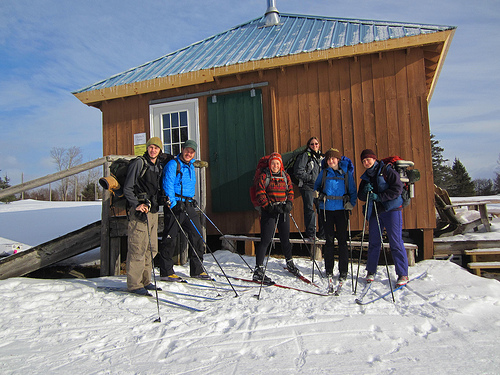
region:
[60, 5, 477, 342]
six people ready to ski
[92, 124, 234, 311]
two men with skis and backpacks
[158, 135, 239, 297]
a skier with a blue jacket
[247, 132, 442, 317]
four women with skis and backpacks on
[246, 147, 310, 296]
woman skier with a red backpack and hat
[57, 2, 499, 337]
skiers in front of a hut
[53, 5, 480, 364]
skiers ready to start their day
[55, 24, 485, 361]
five people with skis and one without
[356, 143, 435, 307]
woman dressed in blue with a red backpack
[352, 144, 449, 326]
a skier dressed in blue with a red backpack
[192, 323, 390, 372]
snow covering the ground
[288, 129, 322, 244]
person standing on a bench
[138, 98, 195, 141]
white door on the building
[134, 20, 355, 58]
tin roof on the building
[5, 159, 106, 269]
ramp up to the building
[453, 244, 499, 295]
steps to the building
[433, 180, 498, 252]
wooden chair on the deck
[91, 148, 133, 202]
back pack on the guy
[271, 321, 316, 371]
floor is white in color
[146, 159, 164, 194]
jacket is black in color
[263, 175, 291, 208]
jacket is red in color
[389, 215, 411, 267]
pants are purple in color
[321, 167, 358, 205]
jacket is blue in color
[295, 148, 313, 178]
jacket is grey in color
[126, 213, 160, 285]
pants are grey in color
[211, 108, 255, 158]
door is green in color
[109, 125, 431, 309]
a group of people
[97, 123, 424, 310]
people standing on the snow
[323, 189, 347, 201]
gray strap around the waist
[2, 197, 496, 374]
white snow on the ground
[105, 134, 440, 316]
people going skiing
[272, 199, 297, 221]
hands on the top of the ski poles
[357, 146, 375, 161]
cap on the head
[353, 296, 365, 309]
top of the ski is bent upwards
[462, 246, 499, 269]
snow on the steps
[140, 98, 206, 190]
window on the side of the building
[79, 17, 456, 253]
wood shed with white door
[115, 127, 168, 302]
man wearing black jacket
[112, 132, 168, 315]
man wearing tan pants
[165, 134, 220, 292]
man wearing blue jacket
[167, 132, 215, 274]
man wearing black pants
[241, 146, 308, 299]
boy wearing red sweater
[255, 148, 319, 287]
boy wearing red hat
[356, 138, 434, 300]
woman wearing purple pants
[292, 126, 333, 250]
woman wearing gray jacket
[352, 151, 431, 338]
woman wearing skiis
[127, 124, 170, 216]
a person wearing a jacket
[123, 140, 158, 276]
man whit a gray sweter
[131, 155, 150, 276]
man whit a brown pants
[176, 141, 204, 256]
man standing on the snow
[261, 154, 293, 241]
man standing on the snow whit a sweter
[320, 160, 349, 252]
person wearing sport kit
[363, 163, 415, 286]
man standing on the snow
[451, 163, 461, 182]
green leaves on the tree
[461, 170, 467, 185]
green leaves on the tree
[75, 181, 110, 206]
green leaves on the tree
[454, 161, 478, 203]
green leaves on the tree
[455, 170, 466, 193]
green leaves on the tree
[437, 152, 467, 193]
green leaves on the tree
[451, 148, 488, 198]
green leaves on the tree